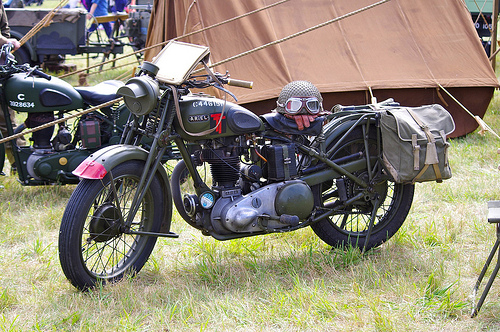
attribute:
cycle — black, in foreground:
[50, 41, 451, 297]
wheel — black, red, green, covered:
[64, 151, 163, 289]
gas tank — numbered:
[186, 97, 252, 133]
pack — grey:
[382, 108, 452, 181]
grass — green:
[156, 254, 326, 331]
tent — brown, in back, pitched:
[140, 2, 490, 142]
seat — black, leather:
[263, 116, 322, 136]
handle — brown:
[226, 82, 253, 90]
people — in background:
[77, 1, 138, 52]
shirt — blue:
[92, 2, 108, 23]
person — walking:
[79, 2, 120, 47]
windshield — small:
[147, 42, 203, 89]